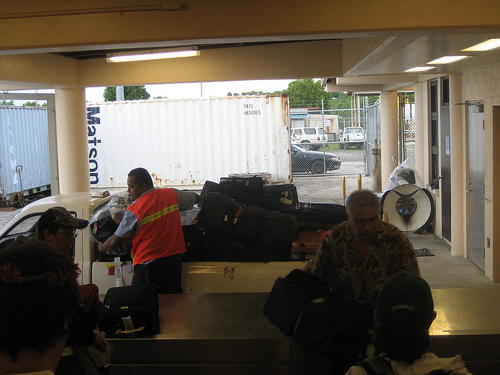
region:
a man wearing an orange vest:
[103, 160, 200, 291]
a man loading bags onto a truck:
[101, 169, 200, 288]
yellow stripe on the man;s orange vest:
[128, 199, 184, 225]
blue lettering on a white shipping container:
[73, 100, 106, 192]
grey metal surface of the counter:
[188, 296, 248, 334]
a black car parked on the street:
[284, 145, 349, 173]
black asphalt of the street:
[342, 147, 361, 159]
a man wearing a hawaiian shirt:
[321, 181, 418, 299]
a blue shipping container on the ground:
[0, 100, 57, 190]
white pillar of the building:
[446, 83, 468, 252]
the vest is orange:
[148, 233, 175, 240]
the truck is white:
[58, 191, 90, 211]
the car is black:
[299, 150, 310, 164]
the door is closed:
[458, 108, 476, 213]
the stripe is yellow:
[147, 202, 169, 219]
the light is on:
[104, 48, 210, 63]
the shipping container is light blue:
[13, 127, 41, 156]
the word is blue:
[81, 97, 106, 184]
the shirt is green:
[331, 245, 353, 276]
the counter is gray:
[195, 303, 242, 337]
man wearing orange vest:
[96, 154, 203, 278]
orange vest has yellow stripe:
[119, 179, 202, 269]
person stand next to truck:
[3, 175, 315, 297]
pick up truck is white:
[12, 172, 305, 306]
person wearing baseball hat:
[355, 265, 456, 367]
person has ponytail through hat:
[358, 261, 448, 369]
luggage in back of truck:
[107, 179, 307, 271]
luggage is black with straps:
[175, 178, 307, 267]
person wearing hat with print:
[21, 195, 98, 251]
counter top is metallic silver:
[157, 283, 295, 344]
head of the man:
[117, 153, 167, 202]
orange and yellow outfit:
[136, 190, 189, 237]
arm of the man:
[86, 221, 136, 273]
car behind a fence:
[288, 140, 338, 178]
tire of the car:
[306, 153, 330, 181]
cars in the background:
[283, 118, 365, 178]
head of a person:
[331, 184, 395, 261]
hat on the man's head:
[356, 258, 439, 365]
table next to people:
[189, 298, 249, 343]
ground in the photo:
[301, 174, 337, 200]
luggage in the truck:
[245, 208, 292, 239]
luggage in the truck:
[300, 237, 324, 253]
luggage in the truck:
[201, 240, 226, 255]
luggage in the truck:
[294, 199, 336, 212]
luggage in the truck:
[268, 183, 290, 200]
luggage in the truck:
[227, 174, 261, 199]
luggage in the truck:
[183, 231, 206, 252]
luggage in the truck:
[98, 221, 124, 248]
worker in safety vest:
[117, 173, 195, 294]